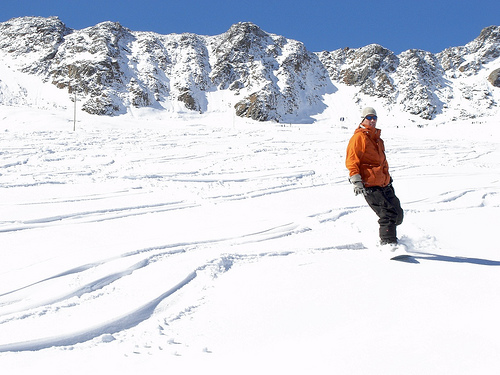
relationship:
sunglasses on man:
[364, 116, 382, 122] [343, 104, 420, 251]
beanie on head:
[367, 106, 379, 125] [352, 110, 387, 131]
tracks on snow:
[25, 225, 353, 335] [4, 115, 498, 355]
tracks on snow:
[24, 131, 321, 208] [4, 115, 498, 355]